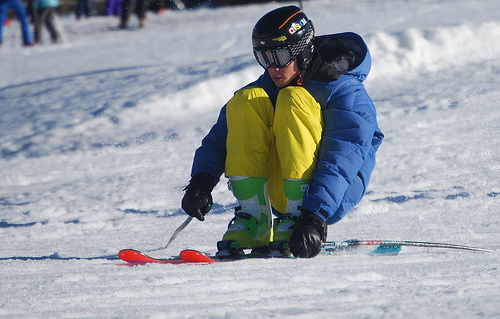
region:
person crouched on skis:
[114, 11, 394, 260]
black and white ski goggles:
[242, 28, 317, 68]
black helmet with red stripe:
[243, 8, 320, 77]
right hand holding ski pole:
[154, 175, 216, 245]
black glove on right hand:
[182, 180, 211, 213]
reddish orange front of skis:
[113, 243, 211, 276]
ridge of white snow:
[111, 20, 496, 100]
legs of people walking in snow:
[3, 2, 154, 59]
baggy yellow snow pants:
[216, 83, 320, 174]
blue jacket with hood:
[182, 30, 376, 225]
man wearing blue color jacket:
[328, 89, 369, 195]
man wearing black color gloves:
[298, 215, 321, 254]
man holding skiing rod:
[323, 239, 437, 246]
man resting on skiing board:
[121, 249, 282, 261]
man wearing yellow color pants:
[228, 99, 310, 169]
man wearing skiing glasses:
[256, 49, 292, 65]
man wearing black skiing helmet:
[260, 10, 310, 37]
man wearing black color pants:
[36, 9, 57, 49]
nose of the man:
[268, 66, 278, 73]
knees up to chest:
[217, 76, 309, 192]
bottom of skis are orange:
[121, 241, 217, 276]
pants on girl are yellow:
[212, 105, 308, 179]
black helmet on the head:
[263, 12, 310, 55]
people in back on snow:
[0, 4, 178, 52]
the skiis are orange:
[118, 248, 213, 261]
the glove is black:
[289, 214, 325, 256]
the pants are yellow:
[227, 88, 319, 211]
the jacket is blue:
[191, 32, 383, 223]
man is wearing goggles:
[252, 45, 294, 66]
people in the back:
[2, 0, 157, 48]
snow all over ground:
[0, 2, 497, 317]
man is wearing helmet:
[252, 5, 311, 52]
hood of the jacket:
[312, 31, 369, 78]